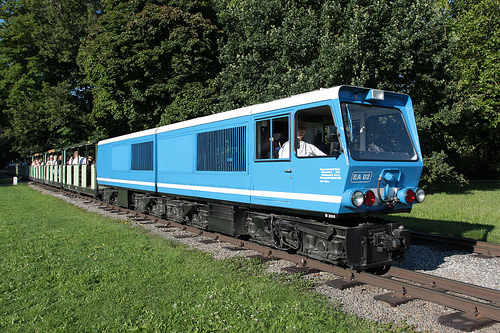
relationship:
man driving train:
[279, 122, 328, 158] [1, 83, 426, 271]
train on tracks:
[1, 83, 426, 271] [31, 179, 500, 323]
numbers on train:
[352, 171, 370, 181] [1, 83, 426, 271]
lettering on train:
[319, 167, 340, 185] [1, 83, 426, 271]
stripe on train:
[97, 177, 342, 205] [1, 83, 426, 271]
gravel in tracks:
[392, 244, 499, 299] [31, 179, 500, 323]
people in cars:
[11, 152, 95, 166] [6, 140, 100, 197]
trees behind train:
[0, 2, 499, 192] [1, 83, 426, 271]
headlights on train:
[353, 189, 424, 209] [1, 83, 426, 271]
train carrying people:
[1, 83, 426, 271] [11, 152, 95, 166]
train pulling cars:
[1, 83, 426, 271] [6, 140, 100, 197]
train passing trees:
[1, 83, 426, 271] [0, 2, 499, 192]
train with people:
[1, 83, 426, 271] [11, 152, 95, 166]